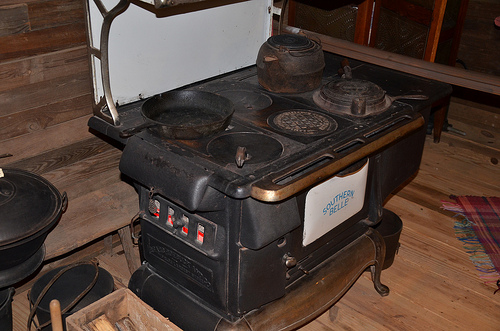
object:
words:
[301, 157, 371, 248]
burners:
[267, 108, 339, 138]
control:
[280, 252, 312, 278]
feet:
[369, 254, 390, 297]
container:
[49, 286, 183, 330]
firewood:
[112, 315, 140, 329]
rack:
[123, 0, 253, 18]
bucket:
[366, 208, 402, 272]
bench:
[48, 287, 194, 330]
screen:
[90, 1, 270, 104]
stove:
[88, 59, 427, 330]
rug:
[437, 195, 498, 294]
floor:
[0, 88, 497, 327]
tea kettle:
[257, 34, 327, 95]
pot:
[27, 265, 115, 330]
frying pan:
[135, 88, 235, 136]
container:
[0, 168, 68, 289]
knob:
[283, 254, 297, 268]